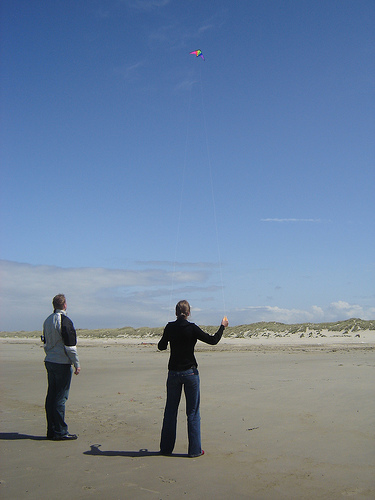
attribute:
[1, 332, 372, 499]
sand — wet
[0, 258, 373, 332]
clouds — white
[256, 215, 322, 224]
clouds — white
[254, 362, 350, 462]
sand — wet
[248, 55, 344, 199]
blue sky — clear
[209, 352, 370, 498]
sand — brown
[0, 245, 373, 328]
clouds — white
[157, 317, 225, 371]
sweater — black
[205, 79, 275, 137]
clouds — white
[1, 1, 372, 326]
sky — blue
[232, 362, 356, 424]
beach — sandy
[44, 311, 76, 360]
jacket — two toned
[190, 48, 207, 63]
kite — colored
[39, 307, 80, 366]
coat — grey white & black